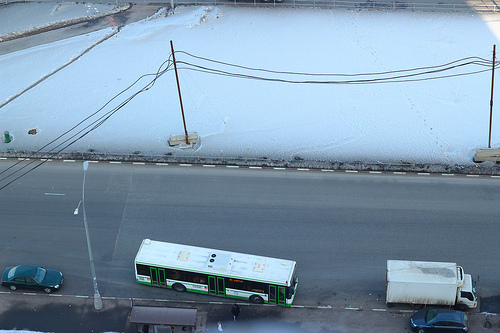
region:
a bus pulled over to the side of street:
[123, 244, 327, 306]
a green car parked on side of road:
[0, 258, 76, 289]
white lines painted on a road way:
[96, 152, 456, 176]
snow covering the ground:
[190, 49, 411, 122]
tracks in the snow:
[391, 89, 468, 142]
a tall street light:
[75, 154, 99, 327]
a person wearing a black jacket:
[228, 299, 241, 322]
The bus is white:
[121, 176, 319, 328]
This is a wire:
[100, 81, 144, 123]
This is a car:
[8, 263, 66, 320]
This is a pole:
[141, 66, 221, 135]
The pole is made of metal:
[161, 91, 183, 128]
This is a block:
[155, 132, 182, 157]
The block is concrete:
[165, 106, 189, 141]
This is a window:
[433, 302, 448, 325]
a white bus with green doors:
[128, 235, 313, 307]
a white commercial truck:
[381, 256, 485, 309]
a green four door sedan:
[1, 258, 66, 295]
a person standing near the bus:
[227, 295, 250, 328]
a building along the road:
[116, 298, 203, 330]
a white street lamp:
[66, 158, 115, 310]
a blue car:
[406, 303, 475, 329]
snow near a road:
[8, 17, 499, 174]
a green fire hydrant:
[1, 124, 17, 144]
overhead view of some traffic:
[5, 10, 485, 325]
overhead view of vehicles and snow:
[25, 60, 480, 320]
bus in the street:
[120, 217, 311, 307]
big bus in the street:
[125, 206, 315, 316]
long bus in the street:
[105, 210, 330, 320]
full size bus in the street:
[100, 200, 315, 322]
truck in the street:
[362, 255, 482, 310]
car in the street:
[0, 250, 71, 305]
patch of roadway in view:
[197, 177, 437, 233]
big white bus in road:
[113, 218, 314, 320]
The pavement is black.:
[276, 195, 379, 240]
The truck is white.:
[378, 256, 482, 305]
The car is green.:
[3, 264, 64, 290]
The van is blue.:
[407, 309, 469, 329]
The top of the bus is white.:
[132, 235, 298, 305]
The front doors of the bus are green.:
[266, 281, 286, 305]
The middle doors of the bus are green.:
[204, 274, 226, 296]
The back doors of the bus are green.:
[148, 266, 169, 287]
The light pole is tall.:
[71, 154, 108, 311]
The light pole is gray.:
[76, 159, 98, 310]